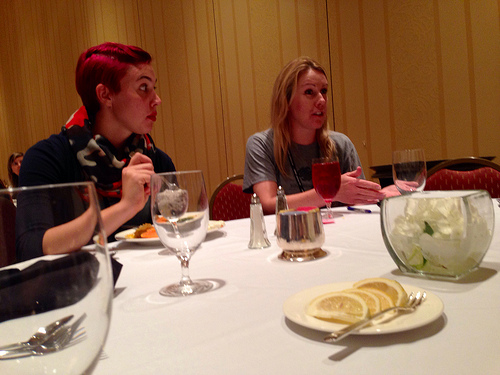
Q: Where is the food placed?
A: Table.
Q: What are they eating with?
A: Forks.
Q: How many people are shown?
A: Two.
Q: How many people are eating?
A: One.